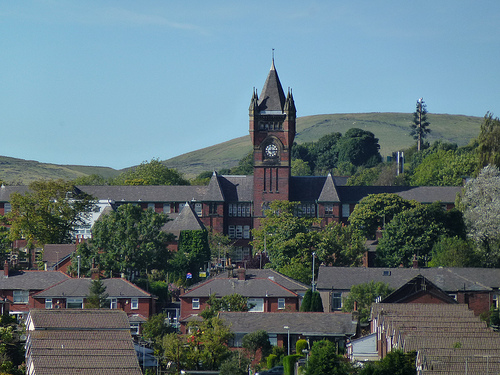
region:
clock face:
[260, 140, 285, 160]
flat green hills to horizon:
[310, 90, 495, 145]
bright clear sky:
[0, 0, 275, 150]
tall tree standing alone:
[406, 90, 431, 155]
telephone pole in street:
[300, 240, 320, 295]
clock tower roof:
[240, 60, 300, 125]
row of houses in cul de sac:
[360, 285, 495, 355]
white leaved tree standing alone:
[446, 150, 491, 260]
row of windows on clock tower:
[225, 200, 255, 215]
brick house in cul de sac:
[36, 265, 158, 335]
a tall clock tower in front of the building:
[242, 50, 289, 257]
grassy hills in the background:
[3, 105, 497, 175]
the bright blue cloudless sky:
[7, 5, 490, 159]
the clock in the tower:
[261, 136, 281, 157]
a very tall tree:
[406, 97, 427, 149]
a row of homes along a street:
[363, 298, 497, 373]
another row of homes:
[17, 304, 147, 372]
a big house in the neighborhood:
[309, 264, 497, 310]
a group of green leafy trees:
[243, 198, 474, 273]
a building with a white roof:
[61, 198, 114, 243]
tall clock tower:
[227, 38, 321, 287]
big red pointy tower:
[242, 36, 301, 281]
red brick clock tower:
[236, 36, 310, 282]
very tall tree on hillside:
[410, 93, 431, 166]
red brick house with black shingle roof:
[176, 269, 312, 341]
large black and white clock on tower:
[259, 134, 284, 165]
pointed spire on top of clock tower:
[252, 36, 291, 115]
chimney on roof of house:
[233, 263, 252, 279]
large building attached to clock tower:
[0, 175, 498, 267]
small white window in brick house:
[125, 292, 143, 314]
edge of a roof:
[352, 315, 353, 327]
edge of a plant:
[412, 223, 419, 234]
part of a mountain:
[386, 109, 398, 125]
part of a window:
[193, 297, 196, 308]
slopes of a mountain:
[203, 145, 215, 156]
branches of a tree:
[299, 194, 374, 257]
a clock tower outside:
[177, 3, 428, 288]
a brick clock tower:
[219, 43, 441, 317]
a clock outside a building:
[149, 57, 433, 267]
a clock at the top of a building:
[229, 60, 364, 218]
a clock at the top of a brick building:
[221, 60, 386, 356]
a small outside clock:
[196, 55, 373, 305]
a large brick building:
[66, 89, 493, 339]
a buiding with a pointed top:
[223, 27, 383, 285]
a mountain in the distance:
[310, 75, 497, 192]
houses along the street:
[67, 207, 489, 369]